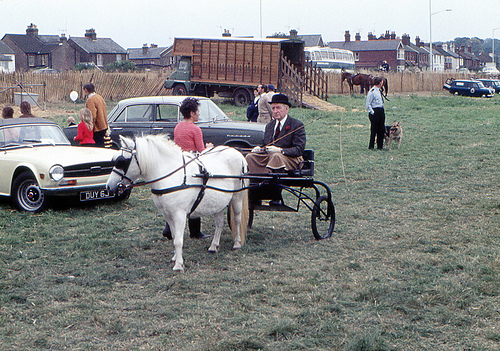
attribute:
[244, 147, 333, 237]
cart — horse-drawn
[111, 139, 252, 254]
horse — white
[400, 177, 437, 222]
ground — looking back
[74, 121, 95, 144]
shirt — red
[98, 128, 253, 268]
white horse — standing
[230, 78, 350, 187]
man — light skinned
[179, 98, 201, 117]
hair — short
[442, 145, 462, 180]
ground — old, white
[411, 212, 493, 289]
grass — area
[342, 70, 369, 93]
horse — standing, brown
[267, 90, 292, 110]
hat — black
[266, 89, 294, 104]
hat — derby, not top